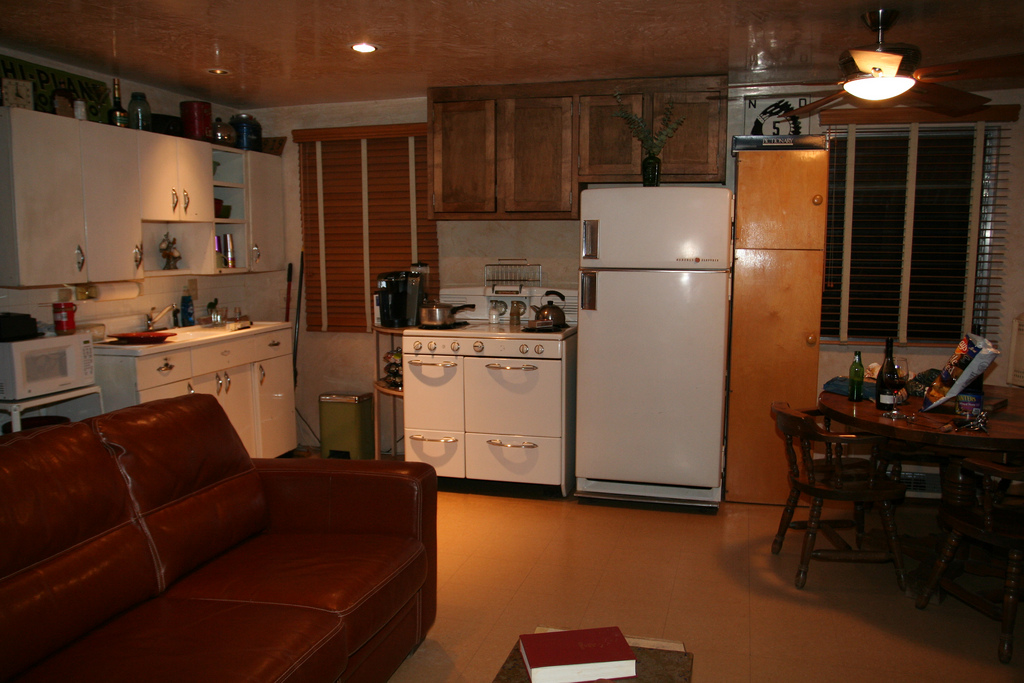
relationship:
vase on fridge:
[644, 155, 663, 185] [578, 183, 737, 509]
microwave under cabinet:
[4, 331, 99, 401] [5, 83, 291, 298]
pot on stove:
[419, 295, 474, 334] [411, 314, 582, 507]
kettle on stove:
[526, 286, 566, 328] [403, 310, 578, 503]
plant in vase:
[588, 81, 683, 140] [634, 132, 663, 184]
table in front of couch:
[497, 621, 693, 680] [6, 380, 441, 679]